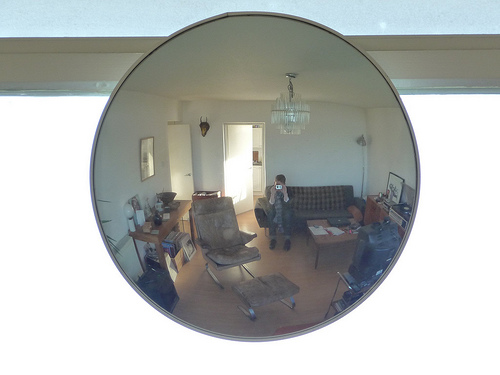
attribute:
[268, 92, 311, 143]
chandelier — large, white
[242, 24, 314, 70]
ceiling — white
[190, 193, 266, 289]
chair — brown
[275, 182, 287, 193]
camera — silver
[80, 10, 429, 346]
mirror — round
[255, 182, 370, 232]
couch — green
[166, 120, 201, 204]
door — white, large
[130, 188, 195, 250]
table — center, brown, small